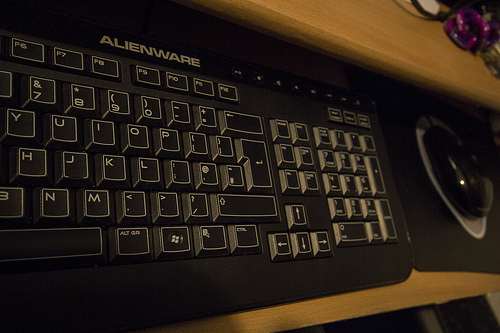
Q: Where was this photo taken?
A: In the classroom.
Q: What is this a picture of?
A: A keyboard.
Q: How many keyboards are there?
A: One.